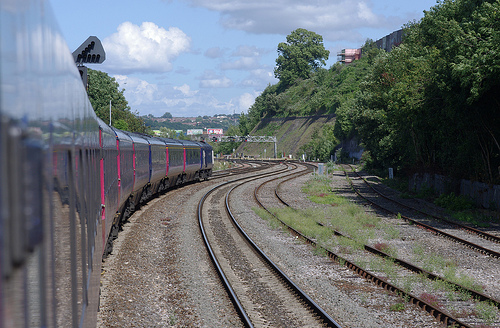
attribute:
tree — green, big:
[273, 28, 328, 84]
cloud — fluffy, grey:
[200, 0, 387, 38]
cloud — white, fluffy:
[103, 18, 186, 72]